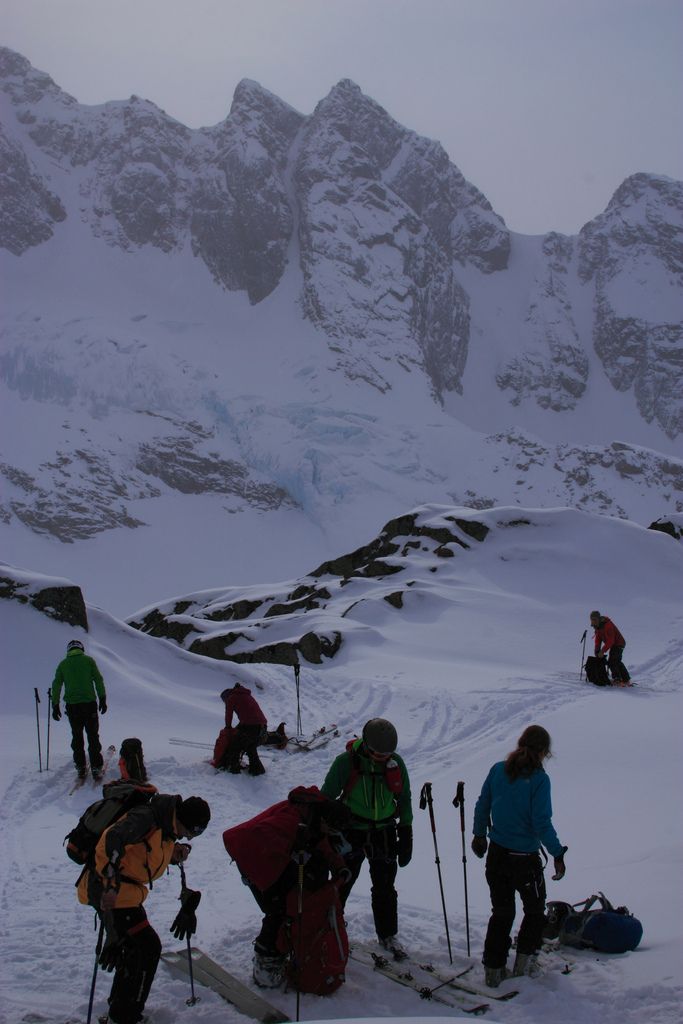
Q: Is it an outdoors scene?
A: Yes, it is outdoors.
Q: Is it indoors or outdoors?
A: It is outdoors.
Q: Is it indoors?
A: No, it is outdoors.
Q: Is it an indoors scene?
A: No, it is outdoors.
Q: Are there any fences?
A: No, there are no fences.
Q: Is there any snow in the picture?
A: Yes, there is snow.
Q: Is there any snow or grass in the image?
A: Yes, there is snow.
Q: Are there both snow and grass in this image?
A: No, there is snow but no grass.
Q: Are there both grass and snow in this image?
A: No, there is snow but no grass.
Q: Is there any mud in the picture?
A: No, there is no mud.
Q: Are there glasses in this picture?
A: No, there are no glasses.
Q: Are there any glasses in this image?
A: No, there are no glasses.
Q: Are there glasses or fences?
A: No, there are no glasses or fences.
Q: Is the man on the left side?
A: Yes, the man is on the left of the image.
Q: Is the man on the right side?
A: No, the man is on the left of the image.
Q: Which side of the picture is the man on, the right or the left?
A: The man is on the left of the image.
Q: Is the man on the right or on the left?
A: The man is on the left of the image.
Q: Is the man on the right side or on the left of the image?
A: The man is on the left of the image.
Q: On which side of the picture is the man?
A: The man is on the left of the image.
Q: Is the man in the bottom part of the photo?
A: Yes, the man is in the bottom of the image.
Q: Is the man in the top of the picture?
A: No, the man is in the bottom of the image.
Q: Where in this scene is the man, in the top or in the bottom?
A: The man is in the bottom of the image.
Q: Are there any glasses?
A: No, there are no glasses.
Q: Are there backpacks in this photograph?
A: Yes, there is a backpack.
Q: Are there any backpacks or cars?
A: Yes, there is a backpack.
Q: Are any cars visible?
A: No, there are no cars.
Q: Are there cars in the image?
A: No, there are no cars.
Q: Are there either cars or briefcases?
A: No, there are no cars or briefcases.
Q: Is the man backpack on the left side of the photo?
A: Yes, the backpack is on the left of the image.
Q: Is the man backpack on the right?
A: No, the backpack is on the left of the image.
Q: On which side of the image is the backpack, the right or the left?
A: The backpack is on the left of the image.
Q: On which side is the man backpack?
A: The backpack is on the left of the image.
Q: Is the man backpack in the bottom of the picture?
A: Yes, the backpack is in the bottom of the image.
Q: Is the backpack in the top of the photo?
A: No, the backpack is in the bottom of the image.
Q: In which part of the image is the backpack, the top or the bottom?
A: The backpack is in the bottom of the image.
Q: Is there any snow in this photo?
A: Yes, there is snow.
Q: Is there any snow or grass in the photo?
A: Yes, there is snow.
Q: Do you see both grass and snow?
A: No, there is snow but no grass.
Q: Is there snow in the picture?
A: Yes, there is snow.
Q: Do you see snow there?
A: Yes, there is snow.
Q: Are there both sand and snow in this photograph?
A: No, there is snow but no sand.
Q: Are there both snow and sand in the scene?
A: No, there is snow but no sand.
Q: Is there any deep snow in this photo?
A: Yes, there is deep snow.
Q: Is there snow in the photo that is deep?
A: Yes, there is deep snow.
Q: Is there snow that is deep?
A: Yes, there is snow that is deep.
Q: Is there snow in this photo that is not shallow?
A: Yes, there is deep snow.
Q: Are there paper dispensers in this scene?
A: No, there are no paper dispensers.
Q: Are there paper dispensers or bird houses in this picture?
A: No, there are no paper dispensers or bird houses.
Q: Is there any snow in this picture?
A: Yes, there is snow.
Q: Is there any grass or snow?
A: Yes, there is snow.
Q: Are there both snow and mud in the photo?
A: No, there is snow but no mud.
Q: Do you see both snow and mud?
A: No, there is snow but no mud.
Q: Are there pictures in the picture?
A: No, there are no pictures.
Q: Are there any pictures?
A: No, there are no pictures.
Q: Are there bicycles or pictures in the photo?
A: No, there are no pictures or bicycles.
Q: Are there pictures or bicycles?
A: No, there are no pictures or bicycles.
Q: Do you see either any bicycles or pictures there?
A: No, there are no pictures or bicycles.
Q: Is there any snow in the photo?
A: Yes, there is snow.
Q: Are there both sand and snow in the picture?
A: No, there is snow but no sand.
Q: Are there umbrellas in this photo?
A: No, there are no umbrellas.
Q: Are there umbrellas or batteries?
A: No, there are no umbrellas or batteries.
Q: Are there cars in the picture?
A: No, there are no cars.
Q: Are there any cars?
A: No, there are no cars.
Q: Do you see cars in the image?
A: No, there are no cars.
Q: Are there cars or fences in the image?
A: No, there are no cars or fences.